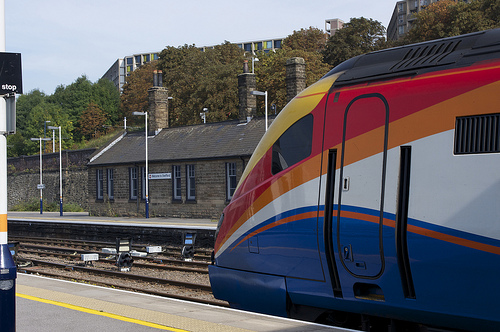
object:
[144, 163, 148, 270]
pole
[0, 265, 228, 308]
tracks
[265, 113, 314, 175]
window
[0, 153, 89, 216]
wall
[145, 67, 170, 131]
chimneys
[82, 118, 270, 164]
roof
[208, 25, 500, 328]
train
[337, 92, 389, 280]
door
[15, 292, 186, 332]
line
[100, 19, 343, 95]
buildings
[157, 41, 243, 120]
trees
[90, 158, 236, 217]
wall